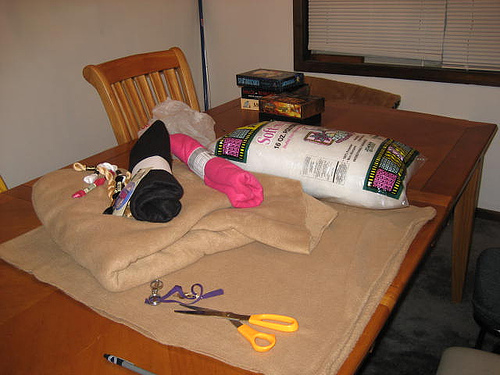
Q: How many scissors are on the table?
A: 1.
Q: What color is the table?
A: Brown.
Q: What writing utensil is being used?
A: Pen.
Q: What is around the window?
A: A border.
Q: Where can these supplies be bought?
A: Crafts store.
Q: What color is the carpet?
A: Grey.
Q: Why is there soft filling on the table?
A: To stuff the craft.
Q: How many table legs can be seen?
A: 1.